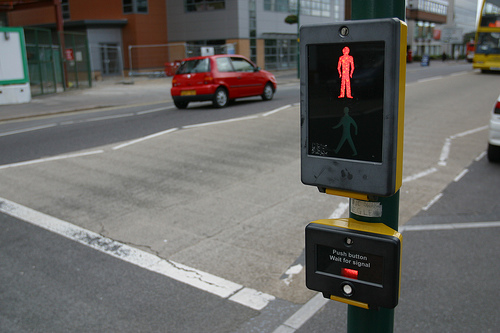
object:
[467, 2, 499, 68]
bus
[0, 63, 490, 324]
road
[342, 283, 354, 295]
button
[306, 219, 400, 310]
machine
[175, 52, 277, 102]
car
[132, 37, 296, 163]
car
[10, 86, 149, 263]
street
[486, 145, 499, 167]
tire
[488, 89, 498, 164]
vehicle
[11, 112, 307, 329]
road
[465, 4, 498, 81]
bus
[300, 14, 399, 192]
crosswalk signals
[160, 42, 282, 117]
car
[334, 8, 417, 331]
green post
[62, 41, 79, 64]
red sign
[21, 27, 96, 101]
fence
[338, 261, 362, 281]
light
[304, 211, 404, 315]
machine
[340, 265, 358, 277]
red light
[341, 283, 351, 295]
white button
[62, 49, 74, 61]
sign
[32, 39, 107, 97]
gate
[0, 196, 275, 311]
line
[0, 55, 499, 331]
pavement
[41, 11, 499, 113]
building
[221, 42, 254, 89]
windows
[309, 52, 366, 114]
man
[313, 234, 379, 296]
button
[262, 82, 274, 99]
tire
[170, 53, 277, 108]
car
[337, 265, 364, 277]
button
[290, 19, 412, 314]
sign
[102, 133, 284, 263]
street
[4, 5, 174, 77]
bulding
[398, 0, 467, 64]
bulding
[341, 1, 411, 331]
pole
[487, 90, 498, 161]
white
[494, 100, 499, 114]
taillight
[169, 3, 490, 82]
building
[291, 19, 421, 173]
signal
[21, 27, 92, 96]
fence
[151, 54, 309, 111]
car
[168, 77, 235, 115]
plate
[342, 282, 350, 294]
button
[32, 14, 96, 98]
green gate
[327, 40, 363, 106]
person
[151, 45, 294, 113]
car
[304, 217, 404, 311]
box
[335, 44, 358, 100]
image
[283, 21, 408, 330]
device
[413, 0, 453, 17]
windows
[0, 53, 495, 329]
street